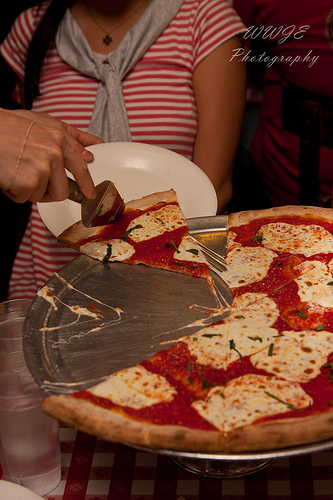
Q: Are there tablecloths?
A: Yes, there is a tablecloth.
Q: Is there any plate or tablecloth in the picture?
A: Yes, there is a tablecloth.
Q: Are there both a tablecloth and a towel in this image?
A: No, there is a tablecloth but no towels.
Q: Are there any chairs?
A: No, there are no chairs.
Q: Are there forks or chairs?
A: No, there are no chairs or forks.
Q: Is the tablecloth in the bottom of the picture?
A: Yes, the tablecloth is in the bottom of the image.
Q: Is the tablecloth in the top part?
A: No, the tablecloth is in the bottom of the image.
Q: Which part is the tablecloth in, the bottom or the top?
A: The tablecloth is in the bottom of the image.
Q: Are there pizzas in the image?
A: Yes, there is a pizza.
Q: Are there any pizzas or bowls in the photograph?
A: Yes, there is a pizza.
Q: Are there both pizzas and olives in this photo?
A: No, there is a pizza but no olives.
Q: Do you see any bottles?
A: No, there are no bottles.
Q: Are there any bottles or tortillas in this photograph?
A: No, there are no bottles or tortillas.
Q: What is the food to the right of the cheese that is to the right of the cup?
A: The food is a pizza.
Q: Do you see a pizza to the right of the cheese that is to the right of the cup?
A: Yes, there is a pizza to the right of the cheese.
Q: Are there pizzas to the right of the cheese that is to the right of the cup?
A: Yes, there is a pizza to the right of the cheese.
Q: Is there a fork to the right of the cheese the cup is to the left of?
A: No, there is a pizza to the right of the cheese.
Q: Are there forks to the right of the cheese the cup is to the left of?
A: No, there is a pizza to the right of the cheese.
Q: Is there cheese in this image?
A: Yes, there is cheese.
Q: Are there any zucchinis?
A: No, there are no zucchinis.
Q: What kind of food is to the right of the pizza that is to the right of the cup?
A: The food is cheese.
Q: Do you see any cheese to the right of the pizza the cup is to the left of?
A: Yes, there is cheese to the right of the pizza.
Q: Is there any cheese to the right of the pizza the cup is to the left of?
A: Yes, there is cheese to the right of the pizza.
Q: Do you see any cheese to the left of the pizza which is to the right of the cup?
A: No, the cheese is to the right of the pizza.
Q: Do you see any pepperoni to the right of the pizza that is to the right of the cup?
A: No, there is cheese to the right of the pizza.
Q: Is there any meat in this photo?
A: No, there is no meat.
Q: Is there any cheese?
A: Yes, there is cheese.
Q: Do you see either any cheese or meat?
A: Yes, there is cheese.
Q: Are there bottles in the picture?
A: No, there are no bottles.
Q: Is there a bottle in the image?
A: No, there are no bottles.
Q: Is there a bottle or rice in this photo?
A: No, there are no bottles or rice.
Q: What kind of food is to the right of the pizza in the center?
A: The food is cheese.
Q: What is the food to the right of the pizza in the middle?
A: The food is cheese.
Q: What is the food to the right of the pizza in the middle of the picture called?
A: The food is cheese.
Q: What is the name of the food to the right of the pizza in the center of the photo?
A: The food is cheese.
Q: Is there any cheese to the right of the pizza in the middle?
A: Yes, there is cheese to the right of the pizza.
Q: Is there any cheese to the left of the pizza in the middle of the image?
A: No, the cheese is to the right of the pizza.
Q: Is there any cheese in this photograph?
A: Yes, there is cheese.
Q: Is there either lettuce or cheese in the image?
A: Yes, there is cheese.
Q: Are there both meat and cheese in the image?
A: No, there is cheese but no meat.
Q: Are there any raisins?
A: No, there are no raisins.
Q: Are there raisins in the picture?
A: No, there are no raisins.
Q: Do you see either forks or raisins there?
A: No, there are no raisins or forks.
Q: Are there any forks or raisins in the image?
A: No, there are no raisins or forks.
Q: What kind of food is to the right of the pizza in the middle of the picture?
A: The food is cheese.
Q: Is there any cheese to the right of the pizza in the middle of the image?
A: Yes, there is cheese to the right of the pizza.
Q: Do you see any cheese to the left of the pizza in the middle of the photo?
A: No, the cheese is to the right of the pizza.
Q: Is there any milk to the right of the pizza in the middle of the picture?
A: No, there is cheese to the right of the pizza.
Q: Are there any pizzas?
A: Yes, there is a pizza.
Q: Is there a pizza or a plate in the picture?
A: Yes, there is a pizza.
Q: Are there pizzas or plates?
A: Yes, there is a pizza.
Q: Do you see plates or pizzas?
A: Yes, there is a pizza.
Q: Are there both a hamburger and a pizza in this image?
A: No, there is a pizza but no hamburgers.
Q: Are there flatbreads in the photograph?
A: No, there are no flatbreads.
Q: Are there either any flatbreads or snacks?
A: No, there are no flatbreads or snacks.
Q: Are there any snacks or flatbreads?
A: No, there are no flatbreads or snacks.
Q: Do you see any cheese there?
A: Yes, there is cheese.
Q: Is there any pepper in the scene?
A: No, there are no peppers.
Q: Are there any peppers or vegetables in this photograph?
A: No, there are no peppers or vegetables.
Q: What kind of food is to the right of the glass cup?
A: The food is cheese.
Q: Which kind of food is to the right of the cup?
A: The food is cheese.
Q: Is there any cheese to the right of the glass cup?
A: Yes, there is cheese to the right of the cup.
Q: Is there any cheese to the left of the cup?
A: No, the cheese is to the right of the cup.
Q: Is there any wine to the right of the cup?
A: No, there is cheese to the right of the cup.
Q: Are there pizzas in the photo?
A: Yes, there is a pizza.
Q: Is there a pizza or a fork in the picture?
A: Yes, there is a pizza.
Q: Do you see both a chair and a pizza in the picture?
A: No, there is a pizza but no chairs.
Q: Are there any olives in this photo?
A: No, there are no olives.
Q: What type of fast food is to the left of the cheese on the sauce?
A: The food is a pizza.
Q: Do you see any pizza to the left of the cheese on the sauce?
A: Yes, there is a pizza to the left of the cheese.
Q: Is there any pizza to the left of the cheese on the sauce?
A: Yes, there is a pizza to the left of the cheese.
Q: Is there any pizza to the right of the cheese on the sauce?
A: No, the pizza is to the left of the cheese.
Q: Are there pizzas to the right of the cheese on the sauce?
A: No, the pizza is to the left of the cheese.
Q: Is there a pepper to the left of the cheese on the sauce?
A: No, there is a pizza to the left of the cheese.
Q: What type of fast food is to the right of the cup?
A: The food is a pizza.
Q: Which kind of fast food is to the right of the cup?
A: The food is a pizza.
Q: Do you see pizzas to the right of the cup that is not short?
A: Yes, there is a pizza to the right of the cup.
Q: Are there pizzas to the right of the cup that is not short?
A: Yes, there is a pizza to the right of the cup.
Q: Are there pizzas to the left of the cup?
A: No, the pizza is to the right of the cup.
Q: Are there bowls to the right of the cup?
A: No, there is a pizza to the right of the cup.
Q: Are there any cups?
A: Yes, there is a cup.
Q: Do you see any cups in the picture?
A: Yes, there is a cup.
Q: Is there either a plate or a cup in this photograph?
A: Yes, there is a cup.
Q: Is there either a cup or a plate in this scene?
A: Yes, there is a cup.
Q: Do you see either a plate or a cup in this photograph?
A: Yes, there is a cup.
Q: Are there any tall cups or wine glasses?
A: Yes, there is a tall cup.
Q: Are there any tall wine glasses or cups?
A: Yes, there is a tall cup.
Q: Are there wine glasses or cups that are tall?
A: Yes, the cup is tall.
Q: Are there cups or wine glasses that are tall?
A: Yes, the cup is tall.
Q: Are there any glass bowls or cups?
A: Yes, there is a glass cup.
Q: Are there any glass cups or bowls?
A: Yes, there is a glass cup.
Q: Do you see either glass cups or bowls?
A: Yes, there is a glass cup.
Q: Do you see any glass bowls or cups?
A: Yes, there is a glass cup.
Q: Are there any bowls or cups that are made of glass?
A: Yes, the cup is made of glass.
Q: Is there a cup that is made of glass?
A: Yes, there is a cup that is made of glass.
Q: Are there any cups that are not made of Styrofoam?
A: Yes, there is a cup that is made of glass.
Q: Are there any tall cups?
A: Yes, there is a tall cup.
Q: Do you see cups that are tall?
A: Yes, there is a cup that is tall.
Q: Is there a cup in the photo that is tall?
A: Yes, there is a cup that is tall.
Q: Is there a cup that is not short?
A: Yes, there is a tall cup.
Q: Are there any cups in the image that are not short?
A: Yes, there is a tall cup.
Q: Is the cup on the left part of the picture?
A: Yes, the cup is on the left of the image.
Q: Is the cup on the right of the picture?
A: No, the cup is on the left of the image.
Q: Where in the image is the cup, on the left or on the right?
A: The cup is on the left of the image.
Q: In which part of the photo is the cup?
A: The cup is on the left of the image.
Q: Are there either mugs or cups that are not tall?
A: No, there is a cup but it is tall.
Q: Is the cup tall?
A: Yes, the cup is tall.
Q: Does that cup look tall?
A: Yes, the cup is tall.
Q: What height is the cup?
A: The cup is tall.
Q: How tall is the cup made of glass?
A: The cup is tall.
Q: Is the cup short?
A: No, the cup is tall.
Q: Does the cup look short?
A: No, the cup is tall.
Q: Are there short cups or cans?
A: No, there is a cup but it is tall.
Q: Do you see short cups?
A: No, there is a cup but it is tall.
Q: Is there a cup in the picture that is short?
A: No, there is a cup but it is tall.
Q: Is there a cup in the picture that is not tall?
A: No, there is a cup but it is tall.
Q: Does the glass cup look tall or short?
A: The cup is tall.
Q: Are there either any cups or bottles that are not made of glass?
A: No, there is a cup but it is made of glass.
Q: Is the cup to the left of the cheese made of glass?
A: Yes, the cup is made of glass.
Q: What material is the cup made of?
A: The cup is made of glass.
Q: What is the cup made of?
A: The cup is made of glass.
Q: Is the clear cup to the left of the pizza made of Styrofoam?
A: No, the cup is made of glass.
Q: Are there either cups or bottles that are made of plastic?
A: No, there is a cup but it is made of glass.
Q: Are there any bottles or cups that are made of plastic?
A: No, there is a cup but it is made of glass.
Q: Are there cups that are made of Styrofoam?
A: No, there is a cup but it is made of glass.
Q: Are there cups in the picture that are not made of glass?
A: No, there is a cup but it is made of glass.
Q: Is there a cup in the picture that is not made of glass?
A: No, there is a cup but it is made of glass.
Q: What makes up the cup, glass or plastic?
A: The cup is made of glass.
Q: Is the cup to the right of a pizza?
A: No, the cup is to the left of a pizza.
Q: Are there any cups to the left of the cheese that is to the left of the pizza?
A: Yes, there is a cup to the left of the cheese.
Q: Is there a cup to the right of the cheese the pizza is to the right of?
A: No, the cup is to the left of the cheese.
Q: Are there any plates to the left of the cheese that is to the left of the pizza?
A: No, there is a cup to the left of the cheese.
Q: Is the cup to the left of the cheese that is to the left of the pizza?
A: Yes, the cup is to the left of the cheese.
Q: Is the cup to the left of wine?
A: No, the cup is to the left of the cheese.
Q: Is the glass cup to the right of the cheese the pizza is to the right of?
A: No, the cup is to the left of the cheese.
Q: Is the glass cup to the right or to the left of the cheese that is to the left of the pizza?
A: The cup is to the left of the cheese.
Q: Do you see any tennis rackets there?
A: No, there are no tennis rackets.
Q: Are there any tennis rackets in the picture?
A: No, there are no tennis rackets.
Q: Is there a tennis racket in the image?
A: No, there are no rackets.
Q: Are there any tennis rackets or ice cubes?
A: No, there are no tennis rackets or ice cubes.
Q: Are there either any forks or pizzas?
A: Yes, there is a pizza.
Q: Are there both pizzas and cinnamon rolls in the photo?
A: No, there is a pizza but no cinnamon rolls.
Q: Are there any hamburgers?
A: No, there are no hamburgers.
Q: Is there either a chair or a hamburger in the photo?
A: No, there are no hamburgers or chairs.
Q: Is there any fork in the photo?
A: No, there are no forks.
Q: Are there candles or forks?
A: No, there are no forks or candles.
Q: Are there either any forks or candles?
A: No, there are no forks or candles.